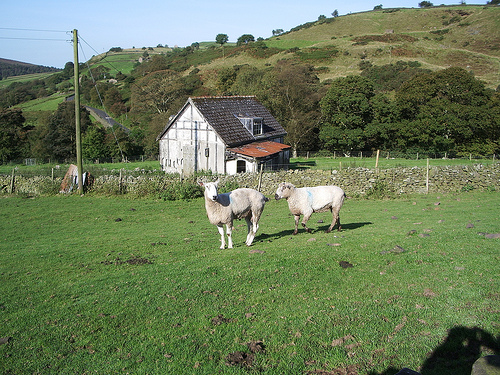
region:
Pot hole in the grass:
[215, 326, 285, 371]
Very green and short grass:
[40, 287, 158, 334]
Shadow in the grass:
[362, 314, 499, 374]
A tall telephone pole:
[68, 26, 88, 198]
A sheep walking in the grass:
[273, 177, 349, 241]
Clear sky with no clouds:
[95, 5, 207, 30]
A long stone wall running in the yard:
[350, 165, 435, 201]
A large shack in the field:
[146, 88, 303, 181]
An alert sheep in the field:
[187, 172, 274, 259]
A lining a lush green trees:
[319, 75, 487, 154]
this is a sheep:
[185, 173, 272, 245]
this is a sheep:
[264, 172, 364, 257]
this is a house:
[147, 90, 315, 205]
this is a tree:
[309, 66, 398, 161]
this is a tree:
[389, 53, 491, 169]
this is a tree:
[31, 90, 95, 168]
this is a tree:
[84, 113, 138, 168]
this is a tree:
[262, 62, 315, 154]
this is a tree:
[3, 108, 32, 168]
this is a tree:
[384, 34, 493, 178]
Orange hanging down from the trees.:
[99, 80, 127, 147]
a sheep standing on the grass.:
[196, 177, 269, 249]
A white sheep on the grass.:
[273, 180, 348, 233]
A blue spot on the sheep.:
[304, 188, 314, 200]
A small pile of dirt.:
[224, 350, 255, 368]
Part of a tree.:
[333, 90, 365, 135]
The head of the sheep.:
[196, 176, 221, 202]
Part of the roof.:
[215, 111, 229, 126]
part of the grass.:
[63, 253, 100, 307]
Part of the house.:
[174, 131, 196, 146]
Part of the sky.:
[111, 21, 145, 33]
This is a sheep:
[263, 177, 365, 234]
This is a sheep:
[188, 173, 273, 253]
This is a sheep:
[273, 178, 358, 240]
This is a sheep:
[188, 168, 273, 259]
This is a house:
[149, 85, 291, 182]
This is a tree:
[272, 57, 317, 169]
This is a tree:
[334, 68, 391, 160]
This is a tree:
[434, 70, 479, 170]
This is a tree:
[148, 59, 179, 147]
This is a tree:
[54, 91, 94, 171]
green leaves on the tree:
[418, 121, 438, 144]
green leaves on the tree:
[386, 65, 396, 90]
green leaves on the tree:
[437, 129, 444, 138]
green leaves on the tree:
[388, 123, 408, 145]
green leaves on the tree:
[347, 97, 363, 117]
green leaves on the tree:
[332, 111, 350, 138]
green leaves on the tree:
[270, 72, 292, 101]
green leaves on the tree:
[236, 52, 255, 78]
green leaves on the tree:
[118, 112, 150, 147]